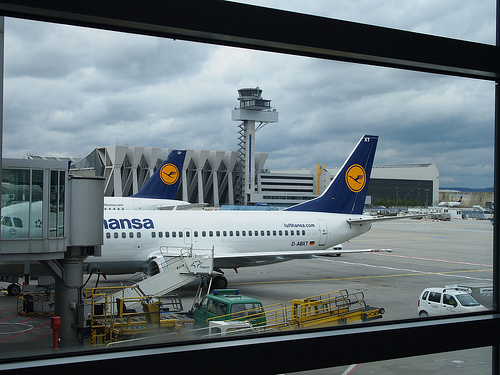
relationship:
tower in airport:
[231, 86, 278, 203] [0, 86, 499, 373]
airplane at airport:
[0, 149, 209, 236] [0, 86, 499, 373]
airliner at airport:
[2, 133, 449, 298] [0, 86, 499, 373]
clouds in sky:
[0, 0, 498, 188] [0, 6, 498, 188]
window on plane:
[193, 230, 199, 237] [85, 132, 447, 288]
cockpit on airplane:
[4, 199, 41, 235] [0, 146, 189, 236]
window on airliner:
[149, 227, 159, 239] [2, 133, 449, 298]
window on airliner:
[184, 227, 191, 237] [2, 133, 449, 298]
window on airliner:
[226, 229, 234, 237] [2, 133, 449, 298]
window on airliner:
[241, 230, 248, 237] [2, 133, 449, 298]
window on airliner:
[266, 230, 271, 236] [2, 133, 449, 298]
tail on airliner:
[283, 132, 381, 216] [2, 133, 449, 298]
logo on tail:
[343, 161, 370, 192] [283, 132, 381, 216]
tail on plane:
[130, 148, 187, 198] [97, 152, 183, 210]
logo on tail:
[156, 160, 178, 185] [130, 148, 187, 198]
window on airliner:
[301, 229, 306, 236] [2, 133, 449, 298]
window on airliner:
[296, 230, 300, 235] [2, 133, 449, 298]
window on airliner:
[275, 227, 286, 237] [2, 133, 449, 298]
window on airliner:
[240, 227, 249, 234] [2, 133, 449, 298]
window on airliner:
[151, 231, 157, 239] [2, 133, 449, 298]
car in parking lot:
[415, 286, 489, 319] [0, 215, 495, 373]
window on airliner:
[300, 226, 308, 235] [2, 133, 449, 298]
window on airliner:
[293, 226, 301, 235] [2, 133, 449, 298]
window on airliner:
[263, 226, 275, 236] [2, 133, 449, 298]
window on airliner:
[222, 226, 227, 236] [2, 133, 449, 298]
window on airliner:
[193, 230, 197, 237] [2, 133, 449, 298]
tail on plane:
[130, 148, 187, 198] [102, 150, 192, 212]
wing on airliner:
[144, 246, 396, 262] [2, 133, 449, 298]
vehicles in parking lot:
[370, 202, 458, 223] [353, 194, 492, 233]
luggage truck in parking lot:
[190, 288, 266, 327] [83, 277, 487, 372]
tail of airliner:
[282, 134, 380, 214] [2, 133, 449, 298]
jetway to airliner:
[95, 246, 214, 316] [2, 133, 449, 298]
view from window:
[3, 15, 498, 357] [2, 1, 498, 372]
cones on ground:
[425, 211, 453, 223] [370, 207, 496, 240]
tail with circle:
[283, 132, 381, 216] [344, 160, 370, 194]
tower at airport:
[231, 86, 278, 203] [2, 82, 442, 214]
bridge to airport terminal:
[0, 155, 107, 355] [25, 80, 442, 212]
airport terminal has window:
[25, 80, 442, 212] [278, 230, 282, 236]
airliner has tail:
[2, 131, 435, 298] [283, 132, 381, 216]